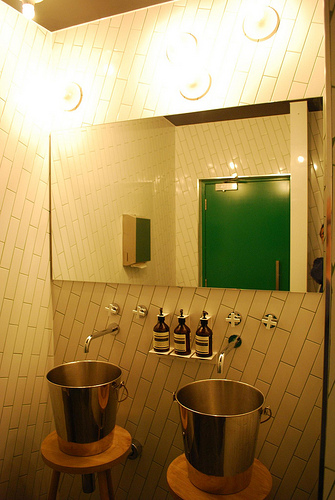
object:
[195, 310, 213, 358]
bottle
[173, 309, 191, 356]
bottle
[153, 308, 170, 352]
bottle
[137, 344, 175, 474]
wall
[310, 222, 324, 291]
person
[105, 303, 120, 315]
knobs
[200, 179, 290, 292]
green door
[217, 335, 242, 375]
faucet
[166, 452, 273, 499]
stool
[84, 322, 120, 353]
faucet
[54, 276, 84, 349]
wall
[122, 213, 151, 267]
dispenser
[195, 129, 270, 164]
tile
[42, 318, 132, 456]
sink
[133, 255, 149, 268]
paper towel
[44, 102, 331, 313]
mirror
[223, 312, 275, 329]
handles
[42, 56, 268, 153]
lights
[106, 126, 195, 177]
wall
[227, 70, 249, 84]
ground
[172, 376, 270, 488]
sinks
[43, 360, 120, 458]
sinks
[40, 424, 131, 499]
stool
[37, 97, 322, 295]
mirror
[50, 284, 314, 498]
tile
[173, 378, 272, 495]
bucket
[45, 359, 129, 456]
bucket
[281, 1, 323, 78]
wall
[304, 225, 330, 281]
reflection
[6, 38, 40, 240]
wall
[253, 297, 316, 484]
wall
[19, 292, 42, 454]
wall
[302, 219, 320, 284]
reflection